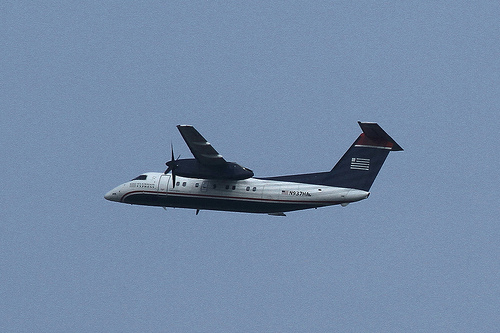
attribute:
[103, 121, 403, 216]
plane — white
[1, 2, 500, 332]
sky — blue, clear, cloudless, dark, limitless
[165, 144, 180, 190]
propeller — black